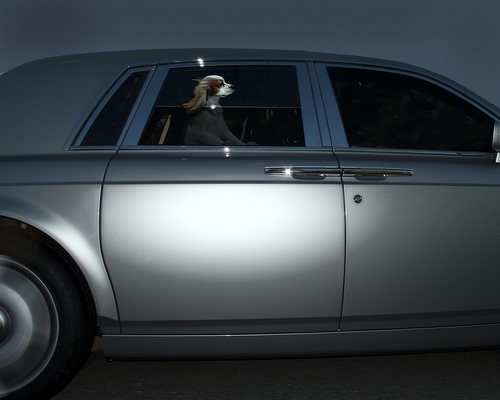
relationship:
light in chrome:
[51, 171, 390, 280] [0, 49, 493, 394]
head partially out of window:
[199, 74, 234, 96] [117, 61, 335, 170]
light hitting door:
[92, 182, 384, 278] [101, 154, 345, 333]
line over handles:
[299, 52, 335, 146] [263, 163, 417, 187]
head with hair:
[191, 71, 236, 103] [181, 78, 208, 113]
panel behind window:
[299, 63, 343, 146] [322, 62, 415, 152]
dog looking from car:
[178, 64, 267, 121] [3, 39, 490, 384]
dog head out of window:
[183, 72, 254, 147] [138, 62, 305, 147]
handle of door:
[284, 163, 393, 187] [93, 50, 352, 330]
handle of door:
[356, 171, 387, 181] [313, 60, 499, 332]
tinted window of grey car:
[323, 65, 496, 155] [3, 48, 496, 352]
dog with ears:
[177, 69, 248, 154] [182, 83, 220, 115]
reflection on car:
[112, 173, 332, 311] [3, 39, 490, 384]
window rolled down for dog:
[140, 106, 305, 146] [183, 72, 254, 147]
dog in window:
[183, 72, 254, 147] [138, 62, 305, 147]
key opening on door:
[352, 192, 362, 204] [313, 60, 499, 332]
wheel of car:
[0, 230, 100, 385] [3, 39, 490, 384]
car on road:
[3, 39, 490, 384] [93, 356, 480, 392]